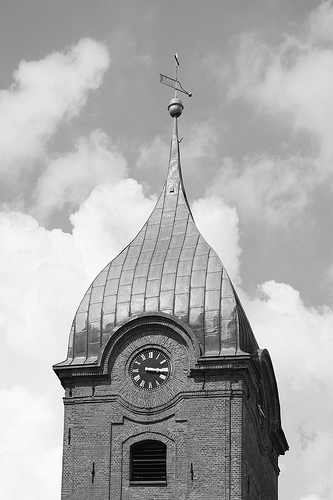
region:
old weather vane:
[146, 38, 201, 123]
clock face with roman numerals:
[129, 337, 211, 419]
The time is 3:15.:
[117, 338, 180, 411]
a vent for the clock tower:
[107, 433, 179, 494]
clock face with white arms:
[250, 383, 274, 429]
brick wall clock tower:
[194, 409, 238, 462]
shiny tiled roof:
[129, 255, 216, 317]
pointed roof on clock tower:
[73, 41, 277, 302]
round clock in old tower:
[125, 346, 177, 416]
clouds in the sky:
[32, 32, 149, 197]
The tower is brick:
[50, 42, 284, 498]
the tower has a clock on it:
[122, 342, 174, 392]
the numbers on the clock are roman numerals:
[127, 347, 175, 390]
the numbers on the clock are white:
[124, 341, 174, 395]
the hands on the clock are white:
[143, 364, 173, 375]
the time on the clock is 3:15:
[120, 342, 176, 393]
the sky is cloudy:
[6, 43, 332, 323]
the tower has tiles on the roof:
[53, 166, 277, 397]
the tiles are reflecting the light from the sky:
[30, 135, 283, 396]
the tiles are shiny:
[35, 162, 269, 387]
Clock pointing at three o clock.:
[129, 340, 180, 392]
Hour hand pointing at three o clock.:
[144, 365, 174, 377]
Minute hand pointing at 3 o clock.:
[143, 362, 171, 375]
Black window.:
[117, 427, 179, 486]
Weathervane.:
[156, 45, 198, 104]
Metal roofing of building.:
[49, 112, 285, 401]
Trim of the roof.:
[36, 355, 260, 382]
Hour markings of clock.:
[128, 341, 177, 390]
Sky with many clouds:
[1, 9, 332, 492]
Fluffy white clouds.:
[5, 0, 330, 497]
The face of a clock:
[126, 343, 175, 389]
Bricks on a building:
[184, 396, 228, 458]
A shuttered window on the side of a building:
[125, 436, 169, 487]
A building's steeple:
[65, 48, 254, 365]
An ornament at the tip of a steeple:
[156, 48, 195, 126]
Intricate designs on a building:
[56, 348, 126, 415]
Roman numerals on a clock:
[133, 345, 166, 367]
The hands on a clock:
[143, 362, 167, 375]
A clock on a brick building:
[100, 332, 197, 410]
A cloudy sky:
[8, 38, 139, 228]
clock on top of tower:
[125, 345, 174, 394]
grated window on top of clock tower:
[125, 436, 175, 489]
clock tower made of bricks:
[45, 259, 287, 497]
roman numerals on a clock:
[138, 351, 173, 364]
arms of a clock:
[144, 364, 168, 372]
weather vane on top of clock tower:
[147, 49, 201, 115]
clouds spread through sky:
[10, 11, 122, 226]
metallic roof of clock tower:
[53, 162, 267, 370]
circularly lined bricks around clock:
[109, 334, 198, 405]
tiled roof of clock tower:
[132, 244, 200, 303]